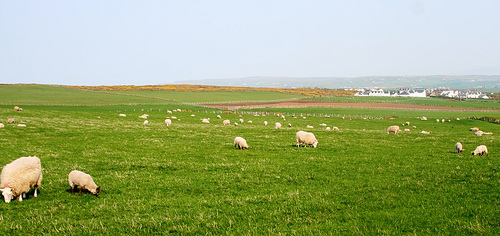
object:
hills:
[163, 84, 215, 92]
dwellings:
[355, 86, 490, 99]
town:
[339, 74, 498, 103]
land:
[270, 101, 417, 108]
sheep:
[1, 155, 45, 203]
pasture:
[0, 85, 497, 235]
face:
[0, 187, 13, 203]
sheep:
[66, 170, 102, 195]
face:
[92, 185, 103, 195]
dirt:
[197, 100, 499, 112]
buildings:
[352, 87, 394, 98]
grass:
[77, 92, 213, 100]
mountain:
[167, 74, 498, 91]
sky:
[1, 1, 499, 76]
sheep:
[233, 136, 250, 149]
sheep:
[384, 125, 402, 134]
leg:
[33, 184, 40, 197]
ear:
[8, 186, 17, 192]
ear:
[0, 187, 5, 194]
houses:
[435, 88, 492, 102]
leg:
[69, 181, 73, 194]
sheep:
[294, 130, 321, 148]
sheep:
[470, 144, 490, 156]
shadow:
[288, 144, 306, 148]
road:
[205, 97, 299, 109]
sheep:
[474, 130, 484, 137]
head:
[88, 183, 102, 194]